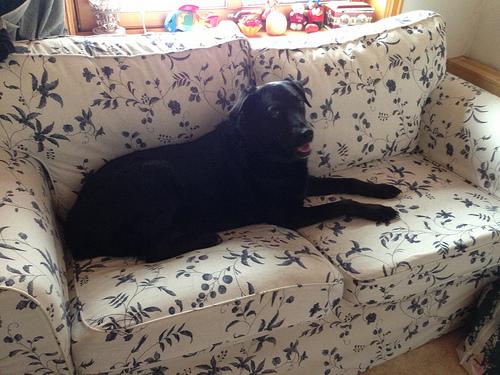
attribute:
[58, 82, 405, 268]
dog — black, lying down, sitting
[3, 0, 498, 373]
sofa — decorated, white, blue, flower-patterned, grey, black, flowered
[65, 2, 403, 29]
window — lighted, wooden, brown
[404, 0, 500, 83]
wall — white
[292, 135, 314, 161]
mouth — open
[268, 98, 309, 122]
eyes — dark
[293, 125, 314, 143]
nose — black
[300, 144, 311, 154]
tongue — pink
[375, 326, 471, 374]
carpet — tan, carpeted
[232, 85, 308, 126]
ears — black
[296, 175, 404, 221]
legs — black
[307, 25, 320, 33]
tomato — red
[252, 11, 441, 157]
cushion — white, black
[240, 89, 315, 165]
head — black